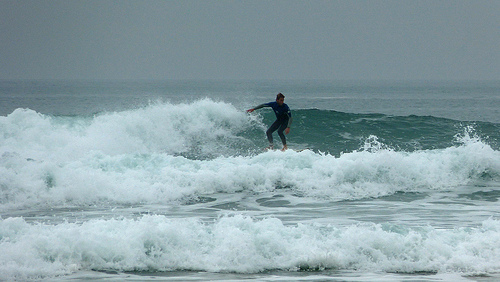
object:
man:
[243, 92, 291, 152]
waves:
[0, 95, 498, 209]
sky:
[0, 1, 498, 82]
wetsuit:
[250, 102, 292, 148]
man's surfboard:
[262, 147, 291, 157]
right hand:
[243, 108, 255, 114]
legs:
[274, 118, 289, 148]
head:
[274, 92, 286, 104]